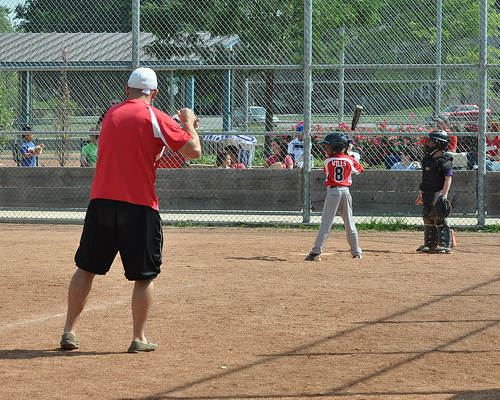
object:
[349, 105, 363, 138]
bat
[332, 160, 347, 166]
name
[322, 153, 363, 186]
jersey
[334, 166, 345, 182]
number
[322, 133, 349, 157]
head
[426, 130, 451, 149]
helmet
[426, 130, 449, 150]
head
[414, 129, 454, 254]
catcher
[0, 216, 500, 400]
field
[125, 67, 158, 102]
head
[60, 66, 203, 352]
man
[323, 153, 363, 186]
shirt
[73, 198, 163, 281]
shorts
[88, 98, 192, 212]
shirt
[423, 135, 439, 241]
gear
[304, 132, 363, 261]
batter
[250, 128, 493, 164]
people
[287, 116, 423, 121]
grass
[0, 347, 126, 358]
shadow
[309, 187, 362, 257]
pants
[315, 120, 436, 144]
rose bushes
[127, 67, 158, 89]
cap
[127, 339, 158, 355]
shoe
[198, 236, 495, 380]
dirt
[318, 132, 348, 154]
cap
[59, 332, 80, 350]
shoes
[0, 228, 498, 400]
ground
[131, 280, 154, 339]
calves